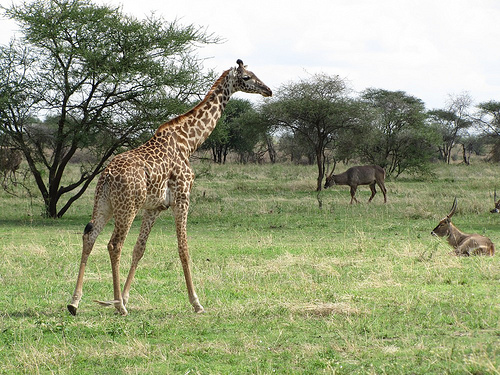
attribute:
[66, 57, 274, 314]
giraffe — tan, brown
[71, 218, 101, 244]
tip — black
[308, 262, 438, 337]
grass — green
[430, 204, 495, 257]
animal — black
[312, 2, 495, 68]
clouds — white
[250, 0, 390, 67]
sky — blue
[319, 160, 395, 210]
animal — brown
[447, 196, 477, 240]
horns — pointy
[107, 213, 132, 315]
leg — white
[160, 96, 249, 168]
neck — long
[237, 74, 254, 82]
eye — black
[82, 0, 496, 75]
cloud — white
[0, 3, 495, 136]
sky — blue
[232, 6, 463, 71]
sky — blue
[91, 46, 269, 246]
neck —  giraffe's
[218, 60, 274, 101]
head —  brown and white,   giraffe's ,  one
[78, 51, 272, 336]
giraffe — walking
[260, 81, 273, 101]
mouth —  closed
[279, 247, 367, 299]
grass — green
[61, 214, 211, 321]
legs — white, brown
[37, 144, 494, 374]
grass — green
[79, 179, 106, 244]
giraffes tail —  giraffe's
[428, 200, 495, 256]
gazelle —  sitting,  light colored ,  one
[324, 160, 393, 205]
animal — brown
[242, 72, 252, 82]
eye —  dark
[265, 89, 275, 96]
nose —  black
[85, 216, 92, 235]
hair —   Black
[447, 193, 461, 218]
horns —   large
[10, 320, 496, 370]
grass —  high